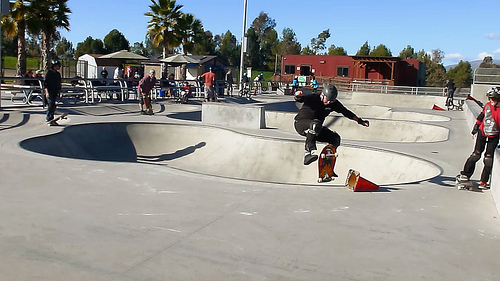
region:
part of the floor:
[340, 221, 417, 275]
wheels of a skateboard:
[321, 148, 340, 163]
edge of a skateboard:
[316, 160, 325, 173]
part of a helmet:
[325, 73, 337, 103]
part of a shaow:
[176, 140, 203, 160]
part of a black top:
[303, 94, 326, 114]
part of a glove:
[348, 111, 375, 133]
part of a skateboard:
[461, 177, 472, 192]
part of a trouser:
[473, 130, 488, 152]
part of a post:
[233, 20, 253, 79]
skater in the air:
[291, 79, 370, 178]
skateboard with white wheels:
[312, 144, 346, 192]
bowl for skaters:
[23, 114, 255, 204]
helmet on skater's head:
[319, 83, 344, 110]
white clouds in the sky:
[448, 32, 490, 62]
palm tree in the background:
[138, 6, 205, 46]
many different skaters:
[36, 48, 251, 135]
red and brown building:
[271, 32, 433, 99]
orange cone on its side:
[343, 165, 392, 207]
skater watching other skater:
[441, 75, 499, 184]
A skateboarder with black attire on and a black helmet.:
[273, 72, 386, 184]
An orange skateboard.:
[310, 140, 348, 188]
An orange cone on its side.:
[337, 163, 391, 205]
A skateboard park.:
[0, 7, 482, 262]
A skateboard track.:
[13, 105, 450, 207]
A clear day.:
[71, 6, 496, 56]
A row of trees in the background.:
[65, 20, 486, 91]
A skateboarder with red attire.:
[442, 79, 497, 199]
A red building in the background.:
[269, 35, 431, 114]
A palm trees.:
[2, 10, 196, 97]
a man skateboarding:
[282, 78, 357, 198]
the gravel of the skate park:
[95, 189, 165, 277]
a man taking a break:
[122, 64, 175, 120]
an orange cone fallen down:
[353, 158, 372, 200]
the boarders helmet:
[315, 83, 337, 103]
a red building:
[264, 45, 419, 81]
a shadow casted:
[157, 148, 241, 158]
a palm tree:
[61, 0, 218, 37]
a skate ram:
[238, 153, 301, 185]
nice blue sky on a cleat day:
[317, 0, 433, 31]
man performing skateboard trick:
[281, 65, 365, 200]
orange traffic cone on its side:
[337, 162, 406, 212]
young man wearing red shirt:
[469, 75, 498, 158]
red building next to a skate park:
[257, 34, 450, 113]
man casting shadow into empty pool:
[24, 46, 212, 194]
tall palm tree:
[141, 1, 198, 81]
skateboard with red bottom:
[305, 141, 343, 191]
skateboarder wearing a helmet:
[283, 77, 370, 188]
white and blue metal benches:
[3, 66, 208, 113]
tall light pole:
[233, 0, 255, 103]